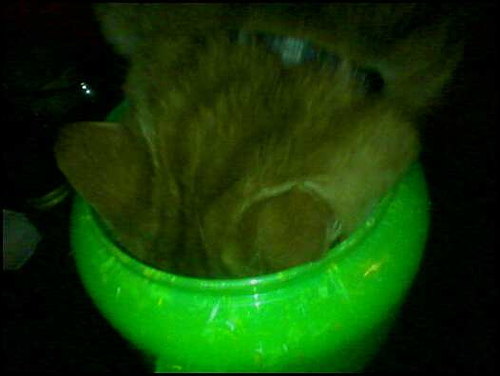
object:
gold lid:
[35, 186, 70, 210]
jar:
[36, 188, 72, 233]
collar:
[202, 28, 387, 101]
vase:
[67, 158, 430, 373]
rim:
[78, 179, 397, 296]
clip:
[246, 30, 390, 100]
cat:
[53, 0, 458, 280]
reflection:
[245, 277, 269, 311]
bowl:
[68, 157, 430, 374]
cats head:
[52, 101, 420, 278]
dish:
[68, 157, 430, 373]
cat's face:
[104, 220, 351, 280]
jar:
[70, 160, 431, 374]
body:
[99, 2, 497, 112]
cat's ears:
[52, 121, 330, 274]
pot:
[69, 160, 432, 373]